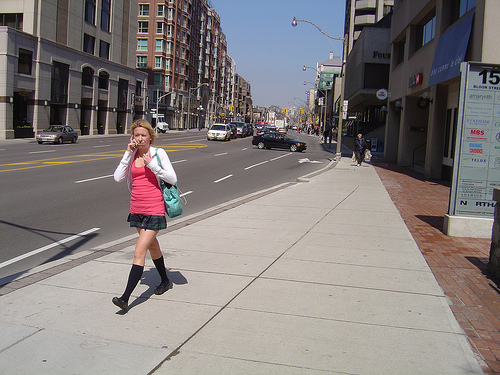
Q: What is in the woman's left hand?
A: A cell phone.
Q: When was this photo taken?
A: Day time.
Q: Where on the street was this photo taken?
A: 15.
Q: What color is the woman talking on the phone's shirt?
A: Pink.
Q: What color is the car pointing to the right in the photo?
A: Black.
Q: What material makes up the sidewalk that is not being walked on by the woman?
A: Brick.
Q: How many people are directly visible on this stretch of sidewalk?
A: Two.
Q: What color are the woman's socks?
A: Black.